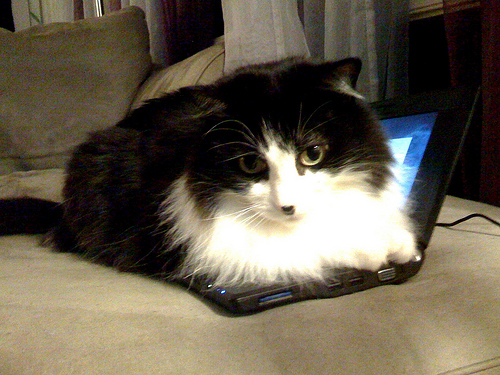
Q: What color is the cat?
A: The cat is black and white.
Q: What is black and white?
A: The cat is black and white.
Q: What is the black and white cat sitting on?
A: The black and white cat is sitting on a lap top.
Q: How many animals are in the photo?
A: One.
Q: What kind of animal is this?
A: Cat.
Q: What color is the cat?
A: Black and white.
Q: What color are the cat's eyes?
A: Yellow and black.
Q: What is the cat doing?
A: Sitting on laptop.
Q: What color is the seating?
A: Tan.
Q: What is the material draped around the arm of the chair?
A: Curtains.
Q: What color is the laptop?
A: Black.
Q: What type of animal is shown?
A: Cat.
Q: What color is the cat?
A: Black and white.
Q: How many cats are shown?
A: 1.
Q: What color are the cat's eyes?
A: Green.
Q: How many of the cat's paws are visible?
A: 0.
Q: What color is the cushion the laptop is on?
A: Tan.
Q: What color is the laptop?
A: Black.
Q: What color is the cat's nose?
A: Black.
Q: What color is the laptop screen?
A: Blue.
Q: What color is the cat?
A: Black and white.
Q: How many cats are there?
A: One.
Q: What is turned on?
A: Computer.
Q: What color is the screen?
A: Blue.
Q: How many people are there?
A: None.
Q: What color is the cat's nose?
A: Black.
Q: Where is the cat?
A: On laptop.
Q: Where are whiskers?
A: On cat's face.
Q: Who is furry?
A: The cat.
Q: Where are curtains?
A: Behind the cat.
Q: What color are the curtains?
A: White.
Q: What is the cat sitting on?
A: A laptop.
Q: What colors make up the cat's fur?
A: Black and white.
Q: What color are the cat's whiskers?
A: White.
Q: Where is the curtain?
A: Behind the cat.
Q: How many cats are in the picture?
A: 1.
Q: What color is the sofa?
A: Tan.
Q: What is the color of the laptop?
A: Black.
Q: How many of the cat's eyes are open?
A: 2.